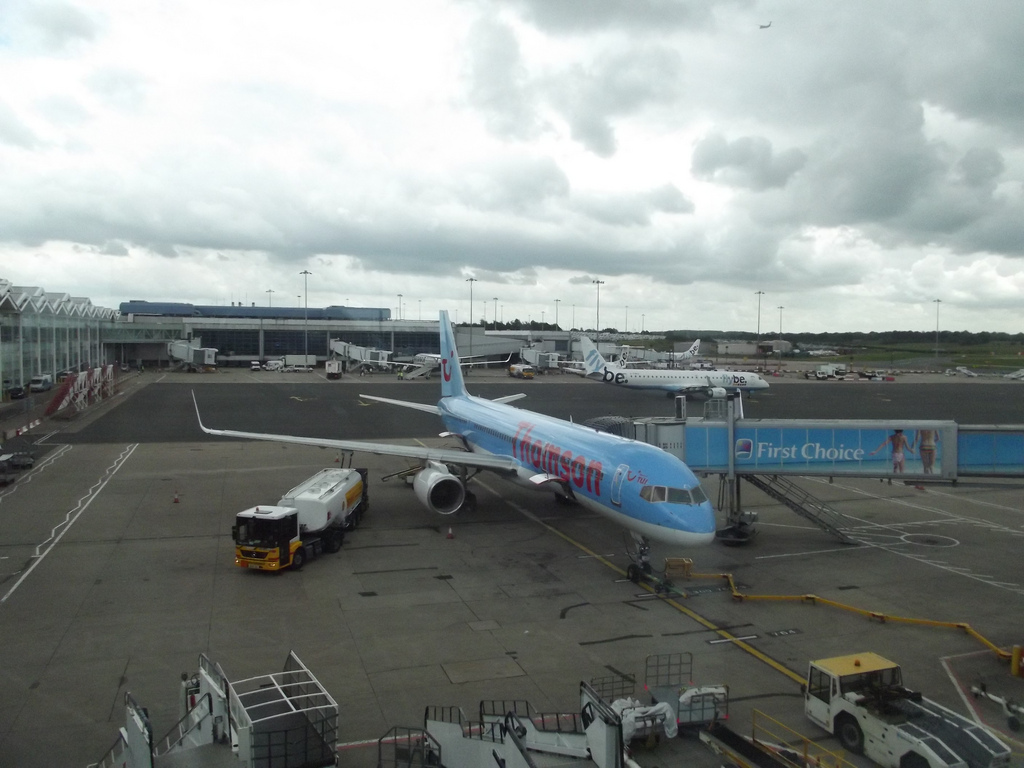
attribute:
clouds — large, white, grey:
[683, 133, 849, 254]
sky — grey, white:
[298, 110, 465, 177]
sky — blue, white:
[816, 80, 965, 269]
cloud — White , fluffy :
[449, 22, 547, 144]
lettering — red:
[500, 402, 607, 502]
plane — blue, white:
[191, 299, 721, 568]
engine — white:
[403, 452, 470, 522]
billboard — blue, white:
[688, 400, 954, 478]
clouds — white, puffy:
[12, 3, 1022, 308]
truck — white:
[226, 458, 371, 571]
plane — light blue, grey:
[185, 305, 730, 601]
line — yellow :
[625, 561, 818, 695]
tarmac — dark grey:
[5, 364, 1021, 754]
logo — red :
[515, 420, 609, 498]